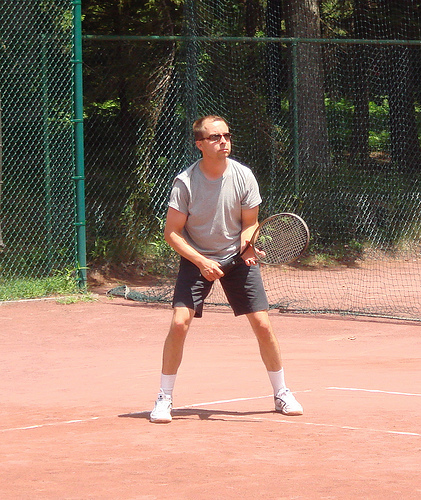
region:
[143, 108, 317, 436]
this is a person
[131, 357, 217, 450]
this is a white shoe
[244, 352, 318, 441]
this is a white shoe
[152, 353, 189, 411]
this is a white socks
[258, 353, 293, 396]
this is a white socks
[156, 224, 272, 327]
the man is in shorts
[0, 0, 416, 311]
this is a fence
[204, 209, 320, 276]
this is a racket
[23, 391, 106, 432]
a chalk mark on the field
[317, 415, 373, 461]
a chalk mark on the field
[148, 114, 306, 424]
man wearing sunglasses and white socks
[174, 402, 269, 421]
shadow on the ground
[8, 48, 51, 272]
green chain link fence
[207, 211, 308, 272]
brown tennis racket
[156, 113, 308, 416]
man holding a tennis racket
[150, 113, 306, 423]
man wearing a gray shirt and white socks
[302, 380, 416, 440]
white lines painted on the court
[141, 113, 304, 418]
man wearing sunglasses and black shorts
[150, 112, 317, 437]
man on a tennis court on a sunny day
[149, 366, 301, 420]
white shoes and white socks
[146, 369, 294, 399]
Two white socks on man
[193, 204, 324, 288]
Black and white tennis racket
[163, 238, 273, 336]
Black tennis shorts on man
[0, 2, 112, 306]
Green piece of chain link fence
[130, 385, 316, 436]
Two black and white tennis shoes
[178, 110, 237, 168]
Man with sunglasses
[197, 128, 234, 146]
Man with dark sunglasses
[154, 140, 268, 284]
Man with gray shirt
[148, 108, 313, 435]
Man playing tennis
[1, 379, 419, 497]
White lines on tennis court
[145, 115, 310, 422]
Person playing tennis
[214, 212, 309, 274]
Tennis racket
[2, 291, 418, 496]
Light red tennis court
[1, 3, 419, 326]
Group of fences used to separate the court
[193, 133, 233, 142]
Pair of sunglasses worn by the person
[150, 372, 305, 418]
Pair of shoes with high top socks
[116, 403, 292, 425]
Shadow of the person on the ground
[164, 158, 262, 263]
Gray short sleeve shirt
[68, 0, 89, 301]
Pole used to connect the fence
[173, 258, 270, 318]
Black short pants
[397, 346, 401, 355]
part of a court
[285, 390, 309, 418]
part of a foot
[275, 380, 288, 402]
part of a sock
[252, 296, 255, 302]
part of a short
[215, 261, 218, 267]
part of an arm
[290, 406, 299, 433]
tip of a shoe